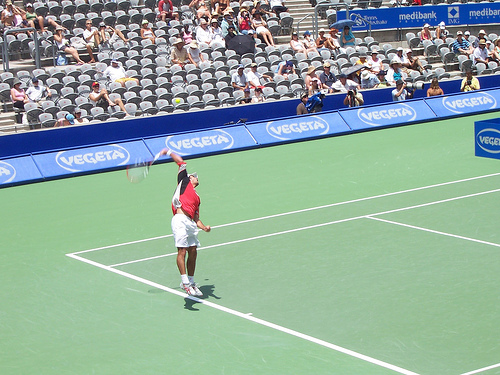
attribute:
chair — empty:
[172, 84, 187, 100]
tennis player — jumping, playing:
[161, 151, 213, 302]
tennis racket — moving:
[127, 150, 165, 184]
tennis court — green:
[5, 107, 498, 374]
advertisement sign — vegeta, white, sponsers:
[266, 113, 329, 139]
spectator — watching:
[86, 79, 115, 108]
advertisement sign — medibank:
[399, 9, 440, 28]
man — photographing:
[346, 86, 362, 109]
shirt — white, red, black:
[464, 79, 478, 90]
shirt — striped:
[174, 162, 203, 224]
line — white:
[68, 250, 434, 374]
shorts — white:
[173, 213, 202, 251]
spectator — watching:
[302, 65, 320, 86]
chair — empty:
[202, 73, 212, 83]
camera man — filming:
[395, 82, 414, 101]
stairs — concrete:
[287, 6, 329, 40]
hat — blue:
[338, 73, 349, 80]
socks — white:
[177, 277, 194, 290]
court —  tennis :
[17, 119, 481, 365]